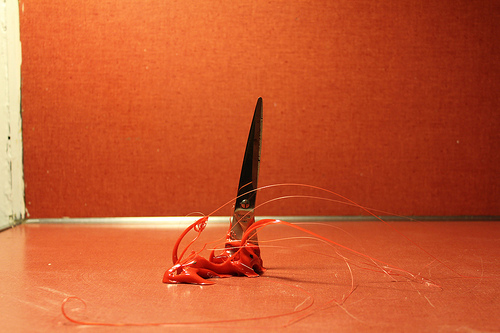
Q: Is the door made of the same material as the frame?
A: Yes, both the door and the frame are made of wood.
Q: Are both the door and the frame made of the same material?
A: Yes, both the door and the frame are made of wood.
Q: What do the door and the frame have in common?
A: The material, both the door and the frame are wooden.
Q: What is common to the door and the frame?
A: The material, both the door and the frame are wooden.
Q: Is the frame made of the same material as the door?
A: Yes, both the frame and the door are made of wood.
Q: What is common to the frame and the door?
A: The material, both the frame and the door are wooden.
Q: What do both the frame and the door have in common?
A: The material, both the frame and the door are wooden.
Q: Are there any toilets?
A: No, there are no toilets.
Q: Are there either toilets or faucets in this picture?
A: No, there are no toilets or faucets.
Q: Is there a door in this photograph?
A: Yes, there is a door.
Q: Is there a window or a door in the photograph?
A: Yes, there is a door.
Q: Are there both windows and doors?
A: No, there is a door but no windows.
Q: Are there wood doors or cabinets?
A: Yes, there is a wood door.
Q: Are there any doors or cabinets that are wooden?
A: Yes, the door is wooden.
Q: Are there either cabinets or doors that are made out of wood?
A: Yes, the door is made of wood.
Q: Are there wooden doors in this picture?
A: Yes, there is a wood door.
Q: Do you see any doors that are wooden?
A: Yes, there is a door that is wooden.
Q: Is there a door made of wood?
A: Yes, there is a door that is made of wood.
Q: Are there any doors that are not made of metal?
A: Yes, there is a door that is made of wood.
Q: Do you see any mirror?
A: No, there are no mirrors.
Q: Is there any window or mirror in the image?
A: No, there are no mirrors or windows.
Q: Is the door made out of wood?
A: Yes, the door is made of wood.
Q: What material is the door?
A: The door is made of wood.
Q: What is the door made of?
A: The door is made of wood.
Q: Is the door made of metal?
A: No, the door is made of wood.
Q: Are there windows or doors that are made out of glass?
A: No, there is a door but it is made of wood.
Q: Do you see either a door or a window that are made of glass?
A: No, there is a door but it is made of wood.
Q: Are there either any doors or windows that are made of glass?
A: No, there is a door but it is made of wood.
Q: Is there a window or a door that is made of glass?
A: No, there is a door but it is made of wood.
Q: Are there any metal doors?
A: No, there is a door but it is made of wood.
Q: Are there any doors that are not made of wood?
A: No, there is a door but it is made of wood.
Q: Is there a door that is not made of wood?
A: No, there is a door but it is made of wood.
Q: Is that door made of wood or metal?
A: The door is made of wood.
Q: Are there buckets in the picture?
A: No, there are no buckets.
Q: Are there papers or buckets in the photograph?
A: No, there are no buckets or papers.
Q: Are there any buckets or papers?
A: No, there are no buckets or papers.